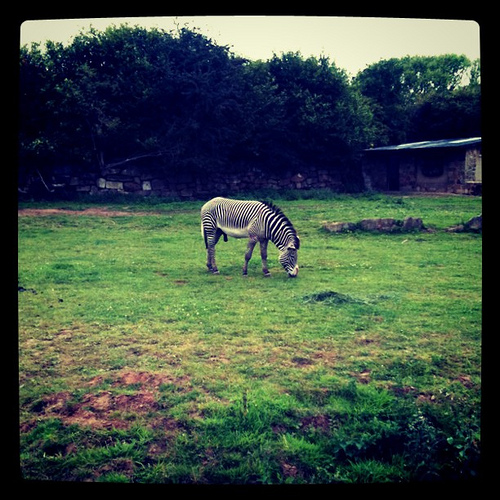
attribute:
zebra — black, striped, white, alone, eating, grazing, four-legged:
[199, 194, 301, 277]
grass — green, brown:
[17, 199, 483, 485]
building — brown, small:
[361, 135, 484, 195]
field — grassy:
[19, 201, 485, 485]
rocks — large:
[322, 213, 483, 235]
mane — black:
[259, 197, 301, 249]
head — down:
[281, 240, 302, 280]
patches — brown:
[18, 324, 482, 484]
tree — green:
[407, 97, 483, 143]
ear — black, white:
[285, 243, 298, 253]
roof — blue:
[365, 137, 482, 151]